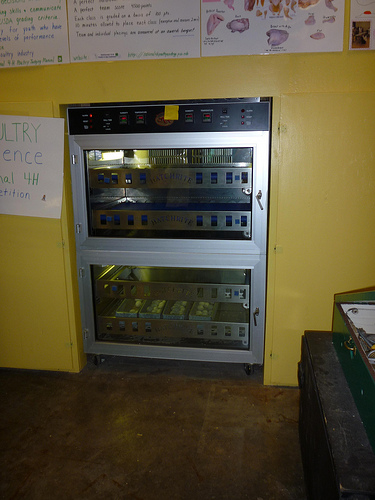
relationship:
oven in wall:
[63, 98, 272, 383] [2, 1, 375, 384]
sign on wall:
[2, 112, 68, 219] [2, 1, 375, 384]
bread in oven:
[114, 291, 144, 315] [63, 98, 272, 383]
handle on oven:
[255, 186, 266, 211] [63, 98, 272, 383]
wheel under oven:
[239, 364, 256, 377] [63, 98, 272, 383]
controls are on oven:
[77, 101, 264, 133] [63, 98, 272, 383]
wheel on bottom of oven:
[239, 364, 256, 377] [63, 98, 272, 383]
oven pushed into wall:
[63, 98, 272, 383] [2, 1, 375, 384]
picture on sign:
[265, 28, 289, 46] [202, 2, 347, 57]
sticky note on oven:
[164, 103, 183, 121] [63, 98, 272, 383]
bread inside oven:
[114, 291, 144, 315] [63, 98, 272, 383]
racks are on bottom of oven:
[94, 268, 255, 352] [63, 98, 272, 383]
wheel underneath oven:
[239, 364, 256, 377] [63, 98, 272, 383]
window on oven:
[82, 147, 253, 241] [63, 98, 272, 383]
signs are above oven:
[2, 2, 375, 69] [63, 98, 272, 383]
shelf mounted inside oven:
[86, 160, 252, 189] [63, 98, 272, 383]